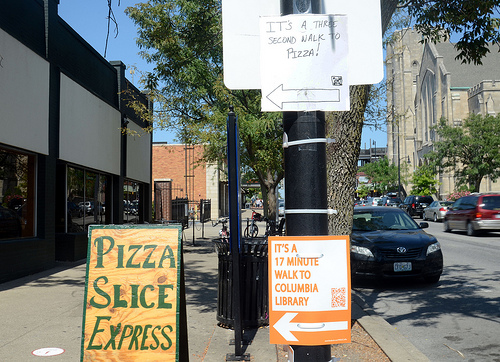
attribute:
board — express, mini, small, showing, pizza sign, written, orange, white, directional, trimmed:
[82, 220, 187, 362]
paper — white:
[257, 16, 351, 112]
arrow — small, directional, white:
[265, 82, 346, 108]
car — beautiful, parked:
[343, 194, 446, 284]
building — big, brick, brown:
[5, 2, 152, 280]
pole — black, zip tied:
[278, 3, 338, 361]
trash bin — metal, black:
[214, 234, 265, 334]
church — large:
[381, 25, 498, 217]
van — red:
[445, 190, 499, 238]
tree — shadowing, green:
[120, 0, 498, 152]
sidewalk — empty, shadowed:
[0, 200, 383, 361]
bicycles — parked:
[214, 215, 289, 253]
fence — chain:
[172, 204, 288, 254]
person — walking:
[179, 209, 195, 251]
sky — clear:
[50, 2, 491, 146]